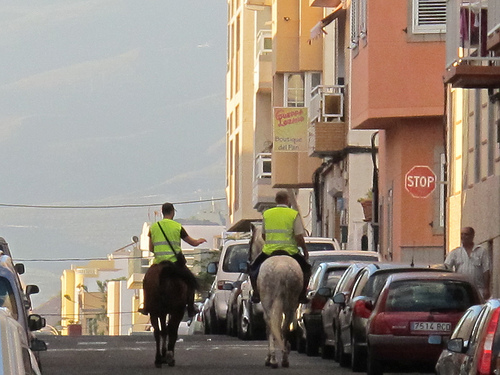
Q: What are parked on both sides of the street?
A: Cars.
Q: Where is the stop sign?
A: On the right.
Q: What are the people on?
A: Horses.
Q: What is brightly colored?
A: Vests.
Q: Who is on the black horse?
A: Man on left.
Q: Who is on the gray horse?
A: Man on right.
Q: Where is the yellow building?
A: Down hill.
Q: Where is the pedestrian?
A: On the far right.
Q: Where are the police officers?
A: On horses.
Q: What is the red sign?
A: Stop sign.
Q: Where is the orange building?
A: On the right.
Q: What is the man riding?
A: A horse.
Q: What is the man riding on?
A: A horse.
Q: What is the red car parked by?
A: A curb.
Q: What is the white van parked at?
A: A curb.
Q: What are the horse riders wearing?
A: Fluorescent green vests with reflective stripes.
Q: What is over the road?
A: Utility lines.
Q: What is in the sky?
A: Light clouds.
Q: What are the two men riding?
A: Horses.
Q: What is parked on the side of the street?
A: A row of parked cars.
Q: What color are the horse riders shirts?
A: Yellow.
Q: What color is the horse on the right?
A: White.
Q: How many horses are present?
A: Two.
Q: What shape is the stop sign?
A: Octagon.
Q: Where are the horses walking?
A: On the street.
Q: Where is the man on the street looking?
A: Towards the horses.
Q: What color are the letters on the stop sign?
A: White.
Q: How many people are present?
A: Three.